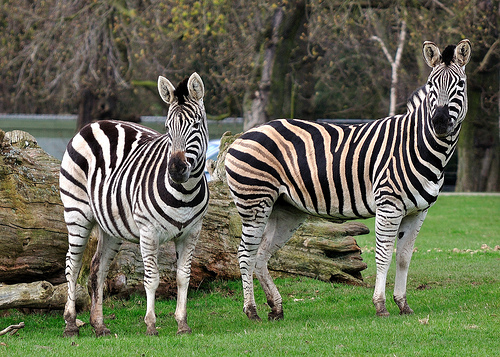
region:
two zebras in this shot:
[47, 14, 482, 336]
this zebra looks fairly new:
[39, 78, 221, 318]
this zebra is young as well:
[224, 28, 486, 335]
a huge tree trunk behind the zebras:
[14, 111, 369, 309]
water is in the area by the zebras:
[13, 114, 402, 162]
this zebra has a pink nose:
[157, 132, 189, 188]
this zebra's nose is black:
[411, 73, 488, 156]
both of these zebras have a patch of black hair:
[131, 16, 471, 106]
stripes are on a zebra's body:
[50, 114, 249, 334]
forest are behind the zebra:
[231, 14, 421, 98]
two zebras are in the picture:
[143, 127, 440, 352]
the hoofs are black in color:
[76, 286, 216, 352]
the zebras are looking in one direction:
[133, 47, 487, 349]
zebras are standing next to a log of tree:
[69, 126, 464, 346]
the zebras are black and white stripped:
[73, 99, 310, 264]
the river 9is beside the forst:
[44, 85, 156, 145]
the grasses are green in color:
[333, 297, 398, 352]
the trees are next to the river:
[169, 12, 361, 98]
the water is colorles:
[27, 116, 70, 154]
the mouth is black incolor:
[156, 147, 224, 197]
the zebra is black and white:
[58, 86, 209, 335]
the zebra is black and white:
[218, 42, 475, 314]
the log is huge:
[6, 128, 368, 308]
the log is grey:
[7, 132, 362, 313]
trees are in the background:
[19, 9, 489, 64]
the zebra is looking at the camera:
[222, 39, 475, 320]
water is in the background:
[24, 87, 67, 147]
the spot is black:
[395, 226, 404, 239]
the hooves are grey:
[140, 315, 210, 332]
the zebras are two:
[43, 35, 498, 320]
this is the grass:
[312, 290, 355, 316]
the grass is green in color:
[278, 320, 305, 347]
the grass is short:
[250, 322, 291, 354]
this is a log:
[0, 145, 394, 274]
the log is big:
[7, 149, 42, 238]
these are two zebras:
[51, 37, 494, 317]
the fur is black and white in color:
[297, 153, 360, 193]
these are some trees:
[202, 9, 408, 104]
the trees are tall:
[325, 15, 358, 47]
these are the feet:
[240, 197, 410, 324]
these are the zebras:
[43, 22, 476, 323]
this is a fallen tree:
[6, 155, 47, 275]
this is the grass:
[296, 320, 401, 348]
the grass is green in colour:
[299, 337, 413, 352]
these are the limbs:
[230, 219, 284, 321]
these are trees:
[207, 10, 409, 95]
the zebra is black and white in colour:
[238, 75, 475, 288]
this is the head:
[158, 77, 210, 184]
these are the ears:
[149, 72, 210, 104]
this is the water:
[34, 115, 69, 135]